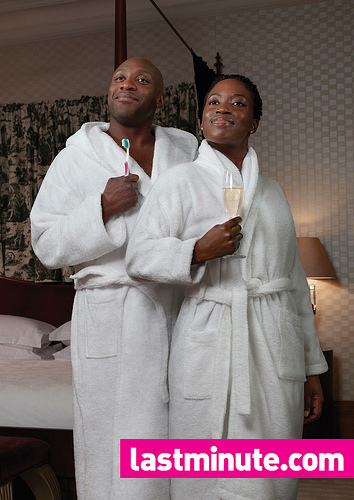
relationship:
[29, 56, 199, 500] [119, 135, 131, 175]
man holding toothbrush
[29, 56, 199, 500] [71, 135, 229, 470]
man wearing bathrobe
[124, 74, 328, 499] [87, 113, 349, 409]
woman wearing bathrobe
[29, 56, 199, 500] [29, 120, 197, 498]
man wearing bathrobe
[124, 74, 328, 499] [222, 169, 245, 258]
woman holding glass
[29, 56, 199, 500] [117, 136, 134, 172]
man holding one toothbrush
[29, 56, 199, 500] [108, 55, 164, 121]
man with head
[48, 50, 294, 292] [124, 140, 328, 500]
two people standing while wearing bathrobe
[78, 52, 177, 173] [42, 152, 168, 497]
man in a robe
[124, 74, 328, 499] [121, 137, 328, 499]
woman in a robe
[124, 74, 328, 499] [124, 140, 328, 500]
woman in a bathrobe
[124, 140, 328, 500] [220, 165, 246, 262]
bathrobe holding glass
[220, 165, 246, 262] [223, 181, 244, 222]
glass of champagne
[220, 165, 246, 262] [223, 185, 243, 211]
glass of champagne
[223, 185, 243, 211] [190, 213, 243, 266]
champagne in a womans hand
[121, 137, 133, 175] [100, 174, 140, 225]
toothbrush in a mans hand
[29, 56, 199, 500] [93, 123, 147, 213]
man holding holding toothbrush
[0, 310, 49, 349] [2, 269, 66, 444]
pillow on a bed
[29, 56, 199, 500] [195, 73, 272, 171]
man and a woman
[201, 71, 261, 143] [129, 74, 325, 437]
head of a woman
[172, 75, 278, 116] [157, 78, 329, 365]
eye of a woman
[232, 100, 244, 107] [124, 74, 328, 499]
eye of a woman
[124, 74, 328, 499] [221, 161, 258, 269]
woman holding glass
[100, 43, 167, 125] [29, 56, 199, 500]
head of man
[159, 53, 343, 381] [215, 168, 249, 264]
woman holding glass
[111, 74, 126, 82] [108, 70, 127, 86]
eye of man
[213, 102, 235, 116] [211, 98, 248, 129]
nose of woman